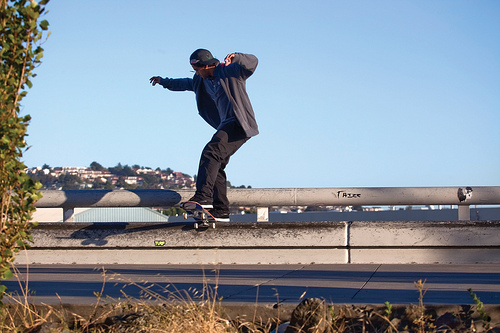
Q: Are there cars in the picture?
A: No, there are no cars.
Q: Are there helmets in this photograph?
A: No, there are no helmets.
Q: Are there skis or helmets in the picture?
A: No, there are no helmets or skis.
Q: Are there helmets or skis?
A: No, there are no helmets or skis.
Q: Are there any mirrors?
A: No, there are no mirrors.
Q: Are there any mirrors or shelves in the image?
A: No, there are no mirrors or shelves.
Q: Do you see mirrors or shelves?
A: No, there are no mirrors or shelves.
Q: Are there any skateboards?
A: Yes, there is a skateboard.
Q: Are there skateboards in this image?
A: Yes, there is a skateboard.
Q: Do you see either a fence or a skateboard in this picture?
A: Yes, there is a skateboard.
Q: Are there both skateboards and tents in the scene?
A: No, there is a skateboard but no tents.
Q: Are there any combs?
A: No, there are no combs.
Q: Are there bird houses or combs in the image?
A: No, there are no combs or bird houses.